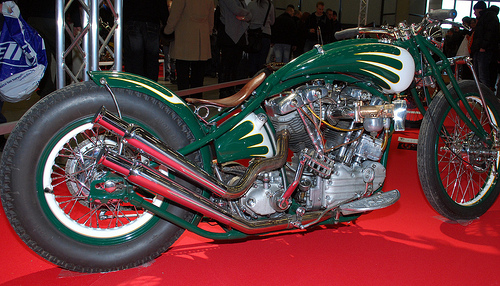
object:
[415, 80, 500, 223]
tire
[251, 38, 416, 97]
tank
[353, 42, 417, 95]
design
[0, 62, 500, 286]
floor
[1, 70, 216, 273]
tire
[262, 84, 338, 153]
engine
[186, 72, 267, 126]
passenger site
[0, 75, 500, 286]
carpet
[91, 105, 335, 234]
pipes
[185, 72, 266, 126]
seat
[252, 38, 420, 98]
fuel tank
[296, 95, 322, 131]
wires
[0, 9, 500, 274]
bike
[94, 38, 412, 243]
frame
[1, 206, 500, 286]
shadow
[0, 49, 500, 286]
platform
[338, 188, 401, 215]
foot support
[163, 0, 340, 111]
person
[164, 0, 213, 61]
coat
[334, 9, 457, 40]
handlebars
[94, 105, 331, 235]
muffler